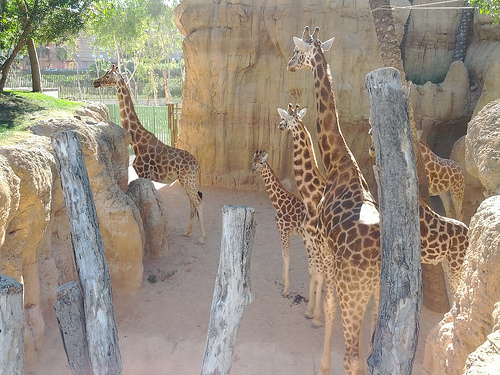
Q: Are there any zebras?
A: No, there are no zebras.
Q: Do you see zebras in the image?
A: No, there are no zebras.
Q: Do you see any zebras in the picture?
A: No, there are no zebras.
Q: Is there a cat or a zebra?
A: No, there are no zebras or cats.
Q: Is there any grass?
A: Yes, there is grass.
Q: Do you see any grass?
A: Yes, there is grass.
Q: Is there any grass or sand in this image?
A: Yes, there is grass.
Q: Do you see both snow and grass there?
A: No, there is grass but no snow.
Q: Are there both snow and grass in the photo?
A: No, there is grass but no snow.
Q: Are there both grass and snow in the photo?
A: No, there is grass but no snow.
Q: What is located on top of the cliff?
A: The grass is on top of the cliff.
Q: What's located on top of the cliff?
A: The grass is on top of the cliff.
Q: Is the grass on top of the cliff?
A: Yes, the grass is on top of the cliff.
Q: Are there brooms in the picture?
A: No, there are no brooms.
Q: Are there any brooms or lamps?
A: No, there are no brooms or lamps.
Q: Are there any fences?
A: Yes, there is a fence.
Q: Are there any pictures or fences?
A: Yes, there is a fence.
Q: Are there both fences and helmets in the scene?
A: No, there is a fence but no helmets.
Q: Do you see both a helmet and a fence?
A: No, there is a fence but no helmets.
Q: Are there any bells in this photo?
A: No, there are no bells.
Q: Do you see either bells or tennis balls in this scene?
A: No, there are no bells or tennis balls.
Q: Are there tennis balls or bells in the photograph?
A: No, there are no bells or tennis balls.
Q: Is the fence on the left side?
A: Yes, the fence is on the left of the image.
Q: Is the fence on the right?
A: No, the fence is on the left of the image.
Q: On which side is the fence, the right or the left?
A: The fence is on the left of the image.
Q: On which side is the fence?
A: The fence is on the left of the image.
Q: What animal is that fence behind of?
A: The fence is behind the giraffe.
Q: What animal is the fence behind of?
A: The fence is behind the giraffe.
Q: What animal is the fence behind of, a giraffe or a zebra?
A: The fence is behind a giraffe.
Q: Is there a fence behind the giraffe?
A: Yes, there is a fence behind the giraffe.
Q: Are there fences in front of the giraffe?
A: No, the fence is behind the giraffe.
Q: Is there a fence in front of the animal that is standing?
A: No, the fence is behind the giraffe.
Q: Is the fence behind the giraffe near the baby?
A: Yes, the fence is behind the giraffe.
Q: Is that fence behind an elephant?
A: No, the fence is behind the giraffe.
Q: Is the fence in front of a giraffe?
A: No, the fence is behind a giraffe.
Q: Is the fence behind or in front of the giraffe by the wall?
A: The fence is behind the giraffe.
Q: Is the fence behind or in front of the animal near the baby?
A: The fence is behind the giraffe.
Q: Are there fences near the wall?
A: Yes, there is a fence near the wall.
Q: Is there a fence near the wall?
A: Yes, there is a fence near the wall.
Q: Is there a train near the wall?
A: No, there is a fence near the wall.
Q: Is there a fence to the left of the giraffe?
A: Yes, there is a fence to the left of the giraffe.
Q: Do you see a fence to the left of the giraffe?
A: Yes, there is a fence to the left of the giraffe.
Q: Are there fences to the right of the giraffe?
A: No, the fence is to the left of the giraffe.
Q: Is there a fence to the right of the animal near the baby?
A: No, the fence is to the left of the giraffe.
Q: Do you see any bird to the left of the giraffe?
A: No, there is a fence to the left of the giraffe.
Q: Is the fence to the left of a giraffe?
A: Yes, the fence is to the left of a giraffe.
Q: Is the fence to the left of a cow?
A: No, the fence is to the left of a giraffe.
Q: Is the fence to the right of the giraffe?
A: No, the fence is to the left of the giraffe.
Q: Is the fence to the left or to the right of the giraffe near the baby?
A: The fence is to the left of the giraffe.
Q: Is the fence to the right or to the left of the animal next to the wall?
A: The fence is to the left of the giraffe.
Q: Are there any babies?
A: Yes, there is a baby.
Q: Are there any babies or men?
A: Yes, there is a baby.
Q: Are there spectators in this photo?
A: No, there are no spectators.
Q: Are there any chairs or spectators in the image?
A: No, there are no spectators or chairs.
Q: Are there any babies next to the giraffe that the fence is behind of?
A: Yes, there is a baby next to the giraffe.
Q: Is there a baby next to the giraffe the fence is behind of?
A: Yes, there is a baby next to the giraffe.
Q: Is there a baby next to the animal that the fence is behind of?
A: Yes, there is a baby next to the giraffe.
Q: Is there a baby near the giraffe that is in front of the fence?
A: Yes, there is a baby near the giraffe.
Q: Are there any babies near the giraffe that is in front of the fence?
A: Yes, there is a baby near the giraffe.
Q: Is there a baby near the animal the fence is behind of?
A: Yes, there is a baby near the giraffe.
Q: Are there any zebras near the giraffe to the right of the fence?
A: No, there is a baby near the giraffe.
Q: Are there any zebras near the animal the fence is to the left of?
A: No, there is a baby near the giraffe.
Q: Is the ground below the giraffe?
A: Yes, the ground is below the giraffe.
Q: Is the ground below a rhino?
A: No, the ground is below the giraffe.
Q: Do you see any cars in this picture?
A: No, there are no cars.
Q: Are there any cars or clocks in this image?
A: No, there are no cars or clocks.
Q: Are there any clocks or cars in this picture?
A: No, there are no cars or clocks.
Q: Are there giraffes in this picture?
A: Yes, there is a giraffe.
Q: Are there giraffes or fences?
A: Yes, there is a giraffe.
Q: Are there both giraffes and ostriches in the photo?
A: No, there is a giraffe but no ostriches.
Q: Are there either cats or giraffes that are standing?
A: Yes, the giraffe is standing.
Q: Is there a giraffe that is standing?
A: Yes, there is a giraffe that is standing.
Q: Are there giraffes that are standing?
A: Yes, there is a giraffe that is standing.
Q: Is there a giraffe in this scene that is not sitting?
A: Yes, there is a giraffe that is standing.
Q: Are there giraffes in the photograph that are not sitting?
A: Yes, there is a giraffe that is standing.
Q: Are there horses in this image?
A: No, there are no horses.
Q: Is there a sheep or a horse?
A: No, there are no horses or sheep.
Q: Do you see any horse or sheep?
A: No, there are no horses or sheep.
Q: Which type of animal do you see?
A: The animal is a giraffe.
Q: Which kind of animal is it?
A: The animal is a giraffe.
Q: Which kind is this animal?
A: This is a giraffe.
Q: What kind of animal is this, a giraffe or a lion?
A: This is a giraffe.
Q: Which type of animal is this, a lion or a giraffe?
A: This is a giraffe.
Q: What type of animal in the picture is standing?
A: The animal is a giraffe.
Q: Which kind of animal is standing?
A: The animal is a giraffe.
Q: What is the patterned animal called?
A: The animal is a giraffe.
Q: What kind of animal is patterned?
A: The animal is a giraffe.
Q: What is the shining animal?
A: The animal is a giraffe.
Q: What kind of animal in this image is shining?
A: The animal is a giraffe.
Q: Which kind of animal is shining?
A: The animal is a giraffe.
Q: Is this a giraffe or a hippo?
A: This is a giraffe.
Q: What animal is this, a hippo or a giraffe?
A: This is a giraffe.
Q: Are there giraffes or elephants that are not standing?
A: No, there is a giraffe but it is standing.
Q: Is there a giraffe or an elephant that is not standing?
A: No, there is a giraffe but it is standing.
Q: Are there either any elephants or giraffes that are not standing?
A: No, there is a giraffe but it is standing.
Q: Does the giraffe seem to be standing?
A: Yes, the giraffe is standing.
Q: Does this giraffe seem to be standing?
A: Yes, the giraffe is standing.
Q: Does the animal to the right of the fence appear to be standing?
A: Yes, the giraffe is standing.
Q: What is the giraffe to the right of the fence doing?
A: The giraffe is standing.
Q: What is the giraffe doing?
A: The giraffe is standing.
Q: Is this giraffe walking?
A: No, the giraffe is standing.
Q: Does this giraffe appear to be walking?
A: No, the giraffe is standing.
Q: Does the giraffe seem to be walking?
A: No, the giraffe is standing.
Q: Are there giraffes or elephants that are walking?
A: No, there is a giraffe but it is standing.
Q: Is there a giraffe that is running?
A: No, there is a giraffe but it is standing.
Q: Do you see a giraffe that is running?
A: No, there is a giraffe but it is standing.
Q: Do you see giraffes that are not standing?
A: No, there is a giraffe but it is standing.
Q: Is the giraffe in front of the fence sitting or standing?
A: The giraffe is standing.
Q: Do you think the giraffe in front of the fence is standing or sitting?
A: The giraffe is standing.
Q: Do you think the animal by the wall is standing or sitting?
A: The giraffe is standing.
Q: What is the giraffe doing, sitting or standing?
A: The giraffe is standing.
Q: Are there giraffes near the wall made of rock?
A: Yes, there is a giraffe near the wall.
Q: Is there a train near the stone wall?
A: No, there is a giraffe near the wall.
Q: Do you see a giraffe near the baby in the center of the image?
A: Yes, there is a giraffe near the baby.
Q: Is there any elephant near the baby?
A: No, there is a giraffe near the baby.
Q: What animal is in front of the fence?
A: The giraffe is in front of the fence.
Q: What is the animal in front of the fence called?
A: The animal is a giraffe.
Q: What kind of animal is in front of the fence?
A: The animal is a giraffe.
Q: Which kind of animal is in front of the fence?
A: The animal is a giraffe.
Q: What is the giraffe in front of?
A: The giraffe is in front of the fence.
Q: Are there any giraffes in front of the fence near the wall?
A: Yes, there is a giraffe in front of the fence.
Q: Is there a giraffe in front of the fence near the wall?
A: Yes, there is a giraffe in front of the fence.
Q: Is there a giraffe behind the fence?
A: No, the giraffe is in front of the fence.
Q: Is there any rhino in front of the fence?
A: No, there is a giraffe in front of the fence.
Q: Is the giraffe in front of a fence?
A: Yes, the giraffe is in front of a fence.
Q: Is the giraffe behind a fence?
A: No, the giraffe is in front of a fence.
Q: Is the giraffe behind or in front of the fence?
A: The giraffe is in front of the fence.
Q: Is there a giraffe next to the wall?
A: Yes, there is a giraffe next to the wall.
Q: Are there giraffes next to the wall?
A: Yes, there is a giraffe next to the wall.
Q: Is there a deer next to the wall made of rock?
A: No, there is a giraffe next to the wall.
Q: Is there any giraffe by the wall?
A: Yes, there is a giraffe by the wall.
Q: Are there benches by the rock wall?
A: No, there is a giraffe by the wall.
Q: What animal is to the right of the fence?
A: The animal is a giraffe.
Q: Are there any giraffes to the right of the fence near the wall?
A: Yes, there is a giraffe to the right of the fence.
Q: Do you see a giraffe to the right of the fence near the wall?
A: Yes, there is a giraffe to the right of the fence.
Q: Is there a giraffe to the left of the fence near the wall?
A: No, the giraffe is to the right of the fence.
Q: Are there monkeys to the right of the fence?
A: No, there is a giraffe to the right of the fence.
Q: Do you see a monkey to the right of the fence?
A: No, there is a giraffe to the right of the fence.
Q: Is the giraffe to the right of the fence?
A: Yes, the giraffe is to the right of the fence.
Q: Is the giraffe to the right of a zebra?
A: No, the giraffe is to the right of the fence.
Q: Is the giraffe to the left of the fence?
A: No, the giraffe is to the right of the fence.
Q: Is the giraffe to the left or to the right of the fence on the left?
A: The giraffe is to the right of the fence.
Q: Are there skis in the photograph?
A: No, there are no skis.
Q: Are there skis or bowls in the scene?
A: No, there are no skis or bowls.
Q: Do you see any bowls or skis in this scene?
A: No, there are no skis or bowls.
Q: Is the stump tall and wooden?
A: Yes, the stump is tall and wooden.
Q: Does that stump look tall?
A: Yes, the stump is tall.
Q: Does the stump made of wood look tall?
A: Yes, the stump is tall.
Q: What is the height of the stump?
A: The stump is tall.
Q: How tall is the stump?
A: The stump is tall.